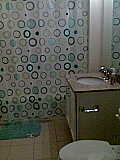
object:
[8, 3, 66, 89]
wall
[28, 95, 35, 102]
circle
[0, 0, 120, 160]
shower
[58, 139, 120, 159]
toilet seat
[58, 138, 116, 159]
lid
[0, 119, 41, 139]
bath mat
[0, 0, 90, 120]
curtain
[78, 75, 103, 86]
bathroom sink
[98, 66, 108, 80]
faucet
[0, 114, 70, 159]
floor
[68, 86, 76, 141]
door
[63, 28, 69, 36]
circle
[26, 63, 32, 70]
circle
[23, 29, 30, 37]
circle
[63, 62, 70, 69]
circle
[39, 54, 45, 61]
circle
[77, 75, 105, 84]
sink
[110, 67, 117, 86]
bottle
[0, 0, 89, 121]
shower curtain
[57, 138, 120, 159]
toilet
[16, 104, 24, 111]
circle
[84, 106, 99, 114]
holder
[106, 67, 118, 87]
faucet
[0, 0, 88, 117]
white background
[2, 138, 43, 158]
tile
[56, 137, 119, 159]
porcelain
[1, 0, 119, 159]
bathroom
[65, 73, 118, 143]
counter